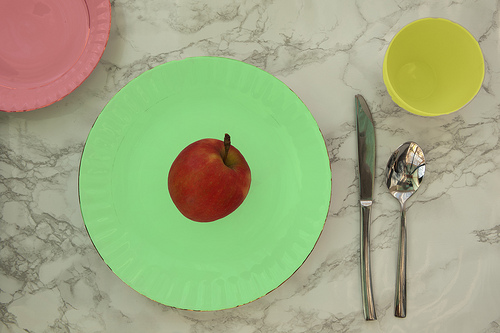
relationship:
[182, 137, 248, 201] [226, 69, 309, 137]
apple on plate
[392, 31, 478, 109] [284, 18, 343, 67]
cup on table